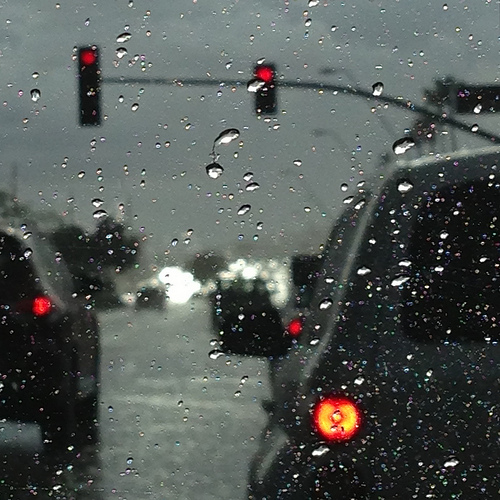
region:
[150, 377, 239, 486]
raining in the picture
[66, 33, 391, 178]
two traffic lights in street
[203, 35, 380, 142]
the traffic light is red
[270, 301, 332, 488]
both cars tail lights are on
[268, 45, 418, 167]
two street lights are shown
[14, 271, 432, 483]
three cars are stopped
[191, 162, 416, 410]
water drops on picture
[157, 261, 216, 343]
lights from other cars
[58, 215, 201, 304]
trees in the background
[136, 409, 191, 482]
street is very wet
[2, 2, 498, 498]
The scene is very rainy.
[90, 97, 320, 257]
Water droplets are on the camera.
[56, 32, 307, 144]
Two traffic lights are visible.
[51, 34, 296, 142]
The traffic lights are red.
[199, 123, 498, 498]
A car is stopped at the lights.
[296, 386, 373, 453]
The car's rear light is lit.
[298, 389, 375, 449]
The rear light is red and orange.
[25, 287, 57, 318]
A red light is on a second car.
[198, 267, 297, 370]
The car's passenger side mirror is visible.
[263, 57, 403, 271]
Street lights are visible.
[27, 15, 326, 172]
street lights with red light lit up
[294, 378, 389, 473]
red brake lights of car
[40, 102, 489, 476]
picture taken through car windshield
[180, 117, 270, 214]
rain drops on car windshield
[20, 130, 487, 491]
cars stopped at red light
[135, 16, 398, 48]
dark cloudy overcast sky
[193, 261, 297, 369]
side view mirror of car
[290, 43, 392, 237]
tall modern street lights not lit up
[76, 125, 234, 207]
cloudy rainy sky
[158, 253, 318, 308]
headlights of cars in distance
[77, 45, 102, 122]
Stoplight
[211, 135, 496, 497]
Side view of a vehicle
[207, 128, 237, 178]
Rain drop from outside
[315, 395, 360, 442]
Red light behind a vehicle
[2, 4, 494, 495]
Window of a vehicle or object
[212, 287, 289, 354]
Mirror of a vehicle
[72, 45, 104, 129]
The stop light is currently flashing red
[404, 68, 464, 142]
Group of tree tops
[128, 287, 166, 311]
Vehicle that's relatively distant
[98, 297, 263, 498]
Gray road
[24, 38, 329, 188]
two red road lights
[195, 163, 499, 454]
car brake lights in a row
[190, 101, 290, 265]
rain droplets on camera lens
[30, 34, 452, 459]
traffic in rainy weather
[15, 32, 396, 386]
traffic stopped at a red light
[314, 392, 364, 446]
red brake light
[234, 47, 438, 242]
street lamps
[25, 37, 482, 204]
black and white picture of red stop light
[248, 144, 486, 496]
cars in a row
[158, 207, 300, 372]
oncoming traffic